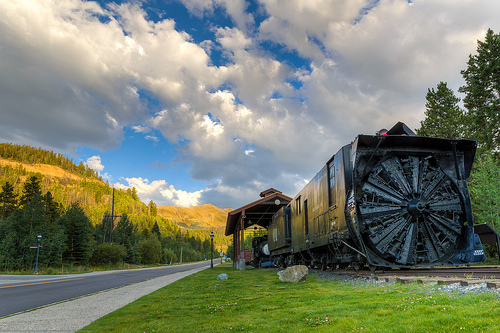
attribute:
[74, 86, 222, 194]
sky — blue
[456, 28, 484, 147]
leaves — green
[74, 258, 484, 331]
grass — green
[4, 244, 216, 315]
road — empty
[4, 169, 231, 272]
trees — pine 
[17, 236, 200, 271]
posts — light 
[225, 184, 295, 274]
station — train , wooden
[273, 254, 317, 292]
rock — large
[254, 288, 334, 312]
grass — some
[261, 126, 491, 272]
train — large, black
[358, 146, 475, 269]
fan — one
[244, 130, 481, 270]
train — one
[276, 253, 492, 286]
tracks — railroad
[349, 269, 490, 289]
ties — railroad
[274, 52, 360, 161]
sky — cloudy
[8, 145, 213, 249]
hills — some